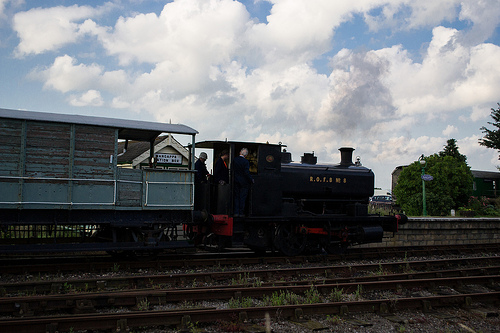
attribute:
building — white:
[105, 125, 179, 182]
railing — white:
[0, 174, 200, 206]